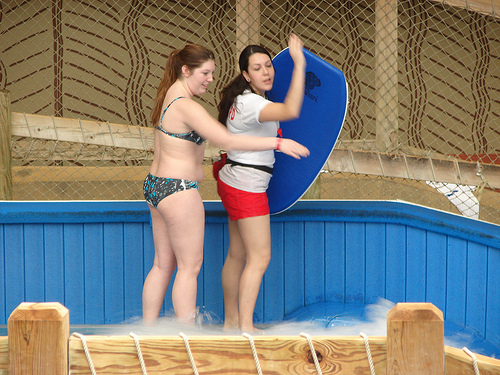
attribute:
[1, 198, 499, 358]
sides — blue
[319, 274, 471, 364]
posts — light brown, wooden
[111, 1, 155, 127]
lines — wavy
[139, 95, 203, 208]
bathing suit — two piece